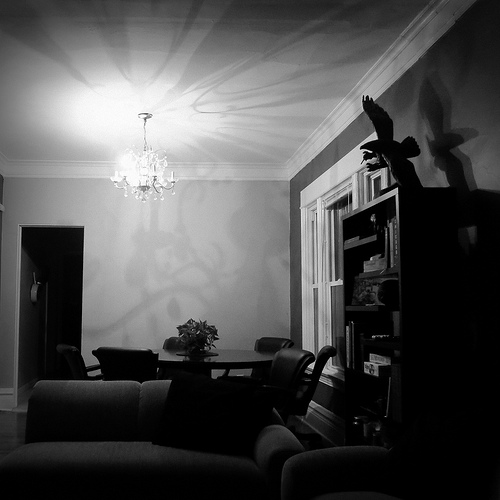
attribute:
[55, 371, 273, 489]
couch — small, black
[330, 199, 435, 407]
book shelf — tall, wood, wooden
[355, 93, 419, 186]
statue — shadow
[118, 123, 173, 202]
light — hanging, on, lighting, shadow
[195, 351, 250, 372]
table — dining room, wooden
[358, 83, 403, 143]
hawk — statue, sideways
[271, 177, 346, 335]
window — large, uncovered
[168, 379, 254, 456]
pillow — large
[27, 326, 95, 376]
kitchen — dark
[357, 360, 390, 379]
box — white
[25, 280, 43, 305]
pan — hanging